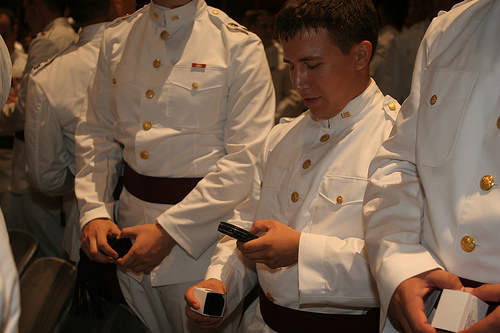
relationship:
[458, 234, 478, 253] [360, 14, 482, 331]
button sewn on shirt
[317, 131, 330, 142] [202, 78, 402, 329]
button sewn on shirt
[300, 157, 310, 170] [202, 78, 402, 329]
button sewn on shirt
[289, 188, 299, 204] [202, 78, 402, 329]
button sewn on shirt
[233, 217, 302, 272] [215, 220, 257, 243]
hand holding cell phone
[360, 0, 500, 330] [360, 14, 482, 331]
man wearing shirt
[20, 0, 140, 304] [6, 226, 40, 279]
man standing behind chair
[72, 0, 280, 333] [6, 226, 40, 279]
man standing behind chair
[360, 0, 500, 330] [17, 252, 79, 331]
man standing behind chair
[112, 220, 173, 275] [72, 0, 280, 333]
hand belonging to man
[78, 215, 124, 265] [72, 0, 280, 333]
hand belonging to man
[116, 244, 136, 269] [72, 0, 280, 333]
finger belonging to man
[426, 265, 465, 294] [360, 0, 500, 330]
finger belonging to man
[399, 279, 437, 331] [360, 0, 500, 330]
finger belonging to man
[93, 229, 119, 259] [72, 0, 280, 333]
finger belonging to man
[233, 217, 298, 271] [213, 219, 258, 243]
hand operating cell phone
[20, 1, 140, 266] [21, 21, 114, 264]
man wearing uniform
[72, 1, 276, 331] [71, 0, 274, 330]
man wearing uniform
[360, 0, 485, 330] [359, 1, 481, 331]
man wearing uniform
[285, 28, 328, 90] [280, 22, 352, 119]
sweat glistening on face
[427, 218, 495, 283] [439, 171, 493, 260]
shiny brass buttons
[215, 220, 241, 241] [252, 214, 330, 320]
cell phone in hand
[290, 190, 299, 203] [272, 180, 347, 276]
button on uniform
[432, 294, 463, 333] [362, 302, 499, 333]
box in hands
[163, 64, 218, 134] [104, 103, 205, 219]
pocket on front of uniform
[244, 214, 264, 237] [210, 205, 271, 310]
thumb pushing phone button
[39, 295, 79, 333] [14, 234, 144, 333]
back of gray chair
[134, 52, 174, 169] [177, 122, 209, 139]
gold buttons going down a shirt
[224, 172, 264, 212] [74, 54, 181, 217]
white button down shirt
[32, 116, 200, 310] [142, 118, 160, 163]
shirt with gold buttons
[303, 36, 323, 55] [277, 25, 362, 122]
shine on face